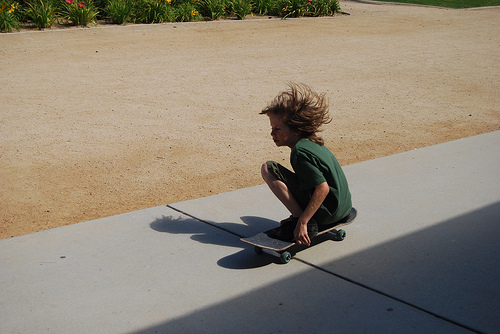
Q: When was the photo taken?
A: Daytime.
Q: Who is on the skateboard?
A: Boy.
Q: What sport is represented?
A: Skateboarding.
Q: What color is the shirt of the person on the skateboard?
A: Green.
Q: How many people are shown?
A: One.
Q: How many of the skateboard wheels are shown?
A: Three.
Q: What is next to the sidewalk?
A: Dirt field.